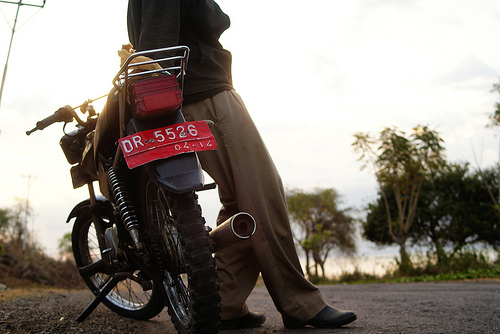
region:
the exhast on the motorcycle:
[209, 210, 263, 249]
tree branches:
[377, 188, 431, 239]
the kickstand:
[65, 292, 106, 319]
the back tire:
[157, 208, 232, 308]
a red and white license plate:
[118, 123, 240, 158]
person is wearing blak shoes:
[313, 310, 356, 331]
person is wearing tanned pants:
[210, 103, 295, 215]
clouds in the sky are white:
[347, 18, 436, 85]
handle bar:
[25, 97, 85, 130]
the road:
[363, 281, 493, 319]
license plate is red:
[113, 119, 216, 169]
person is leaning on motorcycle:
[25, 0, 359, 329]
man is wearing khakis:
[176, 84, 331, 325]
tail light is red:
[131, 73, 181, 113]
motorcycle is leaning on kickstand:
[72, 266, 134, 326]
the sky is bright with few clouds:
[1, 1, 498, 275]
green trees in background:
[283, 81, 499, 280]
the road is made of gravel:
[0, 285, 499, 332]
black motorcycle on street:
[23, 43, 258, 333]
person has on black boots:
[210, 285, 358, 330]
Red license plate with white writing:
[121, 122, 231, 178]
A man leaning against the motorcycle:
[106, 1, 370, 328]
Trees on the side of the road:
[301, 121, 498, 283]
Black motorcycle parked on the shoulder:
[31, 30, 271, 323]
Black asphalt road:
[331, 274, 480, 332]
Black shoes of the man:
[283, 282, 377, 332]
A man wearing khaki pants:
[168, 76, 328, 321]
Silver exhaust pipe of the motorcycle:
[183, 202, 265, 263]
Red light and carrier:
[99, 38, 196, 117]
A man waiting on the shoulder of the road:
[123, 0, 383, 320]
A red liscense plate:
[109, 122, 222, 176]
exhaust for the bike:
[213, 194, 257, 252]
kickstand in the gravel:
[69, 280, 138, 329]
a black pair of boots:
[223, 297, 363, 332]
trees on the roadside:
[334, 110, 499, 270]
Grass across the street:
[411, 264, 498, 285]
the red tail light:
[119, 71, 189, 116]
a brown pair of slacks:
[179, 82, 325, 312]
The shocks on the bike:
[100, 163, 142, 231]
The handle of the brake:
[23, 119, 43, 146]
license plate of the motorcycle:
[114, 116, 224, 178]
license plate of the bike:
[111, 108, 227, 168]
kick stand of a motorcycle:
[63, 262, 134, 327]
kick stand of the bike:
[71, 254, 143, 325]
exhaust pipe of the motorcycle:
[209, 207, 259, 253]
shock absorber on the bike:
[102, 165, 145, 255]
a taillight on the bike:
[125, 67, 192, 116]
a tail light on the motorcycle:
[125, 64, 192, 118]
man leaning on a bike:
[169, 69, 371, 331]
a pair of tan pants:
[189, 74, 347, 325]